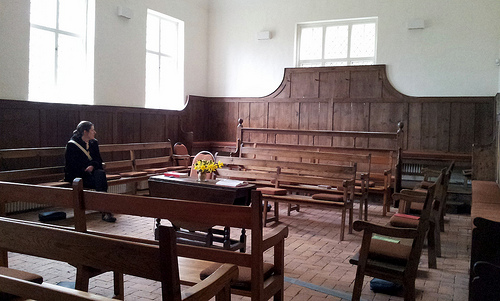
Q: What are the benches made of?
A: Wood.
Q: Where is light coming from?
A: Windows.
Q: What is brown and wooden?
A: Benches.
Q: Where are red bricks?
A: On the floor.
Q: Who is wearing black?
A: The woman.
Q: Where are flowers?
A: On a table.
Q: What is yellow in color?
A: Flowers.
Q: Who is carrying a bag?
A: The woman.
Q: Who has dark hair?
A: Woman sitting.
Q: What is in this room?
A: Table , benches and a woman.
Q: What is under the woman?
A: A brick floor.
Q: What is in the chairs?
A: Books.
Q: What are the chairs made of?
A: Wood.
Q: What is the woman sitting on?
A: Bench.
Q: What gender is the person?
A: Female.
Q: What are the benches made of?
A: Wood.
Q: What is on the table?
A: Flowers.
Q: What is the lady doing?
A: Sitting and looking.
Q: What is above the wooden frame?
A: Windows.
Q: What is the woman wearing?
A: Black dress.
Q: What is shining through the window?
A: Sun.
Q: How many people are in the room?
A: One.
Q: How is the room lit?
A: Sunlight.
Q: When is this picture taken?
A: During the day.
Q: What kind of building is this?
A: Church.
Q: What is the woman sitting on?
A: Bench.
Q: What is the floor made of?
A: Brick.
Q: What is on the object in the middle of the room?
A: Flowers.